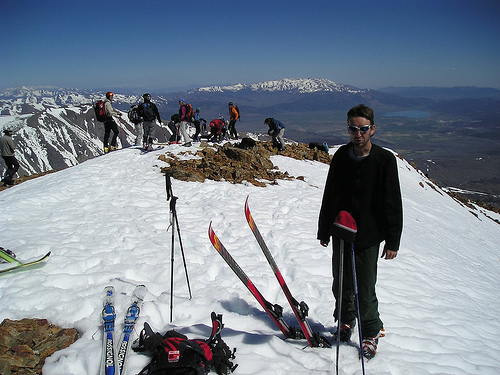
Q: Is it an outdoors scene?
A: Yes, it is outdoors.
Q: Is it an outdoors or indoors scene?
A: It is outdoors.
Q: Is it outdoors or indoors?
A: It is outdoors.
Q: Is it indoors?
A: No, it is outdoors.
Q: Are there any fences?
A: No, there are no fences.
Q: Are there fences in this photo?
A: No, there are no fences.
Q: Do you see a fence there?
A: No, there are no fences.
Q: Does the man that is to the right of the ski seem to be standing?
A: Yes, the man is standing.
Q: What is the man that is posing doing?
A: The man is standing.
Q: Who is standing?
A: The man is standing.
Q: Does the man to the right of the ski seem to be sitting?
A: No, the man is standing.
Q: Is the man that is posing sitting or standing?
A: The man is standing.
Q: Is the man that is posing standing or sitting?
A: The man is standing.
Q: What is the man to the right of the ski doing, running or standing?
A: The man is standing.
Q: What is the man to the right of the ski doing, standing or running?
A: The man is standing.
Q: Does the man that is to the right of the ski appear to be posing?
A: Yes, the man is posing.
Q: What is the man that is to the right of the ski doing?
A: The man is posing.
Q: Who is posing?
A: The man is posing.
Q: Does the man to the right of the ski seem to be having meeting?
A: No, the man is posing.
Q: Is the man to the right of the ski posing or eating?
A: The man is posing.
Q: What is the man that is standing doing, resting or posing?
A: The man is posing.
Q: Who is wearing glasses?
A: The man is wearing glasses.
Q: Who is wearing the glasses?
A: The man is wearing glasses.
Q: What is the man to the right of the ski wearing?
A: The man is wearing glasses.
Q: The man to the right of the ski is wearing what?
A: The man is wearing glasses.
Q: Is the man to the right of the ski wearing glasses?
A: Yes, the man is wearing glasses.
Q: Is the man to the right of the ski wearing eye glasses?
A: No, the man is wearing glasses.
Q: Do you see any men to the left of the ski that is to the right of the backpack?
A: No, the man is to the right of the ski.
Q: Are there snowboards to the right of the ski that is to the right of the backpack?
A: No, there is a man to the right of the ski.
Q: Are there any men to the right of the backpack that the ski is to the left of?
A: Yes, there is a man to the right of the backpack.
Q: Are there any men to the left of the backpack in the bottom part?
A: No, the man is to the right of the backpack.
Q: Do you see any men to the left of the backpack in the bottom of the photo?
A: No, the man is to the right of the backpack.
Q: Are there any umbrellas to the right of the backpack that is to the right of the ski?
A: No, there is a man to the right of the backpack.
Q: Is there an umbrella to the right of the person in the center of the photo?
A: No, there is a man to the right of the person.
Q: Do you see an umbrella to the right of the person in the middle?
A: No, there is a man to the right of the person.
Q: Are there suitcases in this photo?
A: No, there are no suitcases.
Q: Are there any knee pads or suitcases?
A: No, there are no suitcases or knee pads.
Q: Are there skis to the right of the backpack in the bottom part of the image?
A: Yes, there is a ski to the right of the backpack.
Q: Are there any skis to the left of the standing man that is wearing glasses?
A: Yes, there is a ski to the left of the man.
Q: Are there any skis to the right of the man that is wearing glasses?
A: No, the ski is to the left of the man.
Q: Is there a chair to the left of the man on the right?
A: No, there is a ski to the left of the man.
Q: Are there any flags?
A: No, there are no flags.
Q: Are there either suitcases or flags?
A: No, there are no flags or suitcases.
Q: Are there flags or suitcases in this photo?
A: No, there are no flags or suitcases.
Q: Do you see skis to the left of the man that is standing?
A: Yes, there is a ski to the left of the man.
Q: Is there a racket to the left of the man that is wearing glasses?
A: No, there is a ski to the left of the man.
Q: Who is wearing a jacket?
A: The man is wearing a jacket.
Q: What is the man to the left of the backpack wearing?
A: The man is wearing a jacket.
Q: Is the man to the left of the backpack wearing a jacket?
A: Yes, the man is wearing a jacket.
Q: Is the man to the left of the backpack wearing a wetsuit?
A: No, the man is wearing a jacket.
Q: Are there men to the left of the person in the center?
A: Yes, there is a man to the left of the person.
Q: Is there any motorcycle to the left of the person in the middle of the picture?
A: No, there is a man to the left of the person.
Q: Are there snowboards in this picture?
A: No, there are no snowboards.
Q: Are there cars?
A: No, there are no cars.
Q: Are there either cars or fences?
A: No, there are no cars or fences.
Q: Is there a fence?
A: No, there are no fences.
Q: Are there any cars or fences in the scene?
A: No, there are no fences or cars.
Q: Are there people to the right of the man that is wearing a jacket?
A: Yes, there is a person to the right of the man.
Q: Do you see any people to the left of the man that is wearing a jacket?
A: No, the person is to the right of the man.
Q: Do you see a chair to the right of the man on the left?
A: No, there is a person to the right of the man.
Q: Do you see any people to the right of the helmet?
A: Yes, there is a person to the right of the helmet.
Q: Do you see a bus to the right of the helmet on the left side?
A: No, there is a person to the right of the helmet.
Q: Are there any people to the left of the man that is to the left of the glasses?
A: Yes, there is a person to the left of the man.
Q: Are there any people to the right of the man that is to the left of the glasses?
A: No, the person is to the left of the man.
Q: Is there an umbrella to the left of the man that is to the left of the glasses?
A: No, there is a person to the left of the man.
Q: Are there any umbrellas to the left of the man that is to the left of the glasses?
A: No, there is a person to the left of the man.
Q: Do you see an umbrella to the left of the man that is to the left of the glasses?
A: No, there is a person to the left of the man.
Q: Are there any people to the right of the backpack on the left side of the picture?
A: Yes, there is a person to the right of the backpack.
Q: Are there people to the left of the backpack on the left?
A: No, the person is to the right of the backpack.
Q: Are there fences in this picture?
A: No, there are no fences.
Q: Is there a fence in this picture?
A: No, there are no fences.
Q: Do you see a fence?
A: No, there are no fences.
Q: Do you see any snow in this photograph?
A: Yes, there is snow.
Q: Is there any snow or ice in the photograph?
A: Yes, there is snow.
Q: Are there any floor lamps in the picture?
A: No, there are no floor lamps.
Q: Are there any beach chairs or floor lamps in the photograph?
A: No, there are no floor lamps or beach chairs.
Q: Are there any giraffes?
A: No, there are no giraffes.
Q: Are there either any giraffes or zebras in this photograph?
A: No, there are no giraffes or zebras.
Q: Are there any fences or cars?
A: No, there are no cars or fences.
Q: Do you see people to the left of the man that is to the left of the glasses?
A: Yes, there is a person to the left of the man.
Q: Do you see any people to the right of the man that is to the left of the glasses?
A: No, the person is to the left of the man.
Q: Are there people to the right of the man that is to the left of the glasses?
A: No, the person is to the left of the man.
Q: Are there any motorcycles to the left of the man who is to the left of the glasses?
A: No, there is a person to the left of the man.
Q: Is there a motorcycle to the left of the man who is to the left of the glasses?
A: No, there is a person to the left of the man.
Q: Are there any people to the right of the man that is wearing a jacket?
A: Yes, there is a person to the right of the man.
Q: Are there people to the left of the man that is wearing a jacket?
A: No, the person is to the right of the man.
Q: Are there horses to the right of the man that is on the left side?
A: No, there is a person to the right of the man.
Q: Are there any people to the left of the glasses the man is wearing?
A: Yes, there is a person to the left of the glasses.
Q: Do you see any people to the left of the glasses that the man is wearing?
A: Yes, there is a person to the left of the glasses.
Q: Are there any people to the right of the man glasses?
A: No, the person is to the left of the glasses.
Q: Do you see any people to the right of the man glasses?
A: No, the person is to the left of the glasses.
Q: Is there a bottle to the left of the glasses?
A: No, there is a person to the left of the glasses.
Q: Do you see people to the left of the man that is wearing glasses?
A: Yes, there is a person to the left of the man.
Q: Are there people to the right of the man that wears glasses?
A: No, the person is to the left of the man.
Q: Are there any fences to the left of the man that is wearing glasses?
A: No, there is a person to the left of the man.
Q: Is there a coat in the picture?
A: Yes, there is a coat.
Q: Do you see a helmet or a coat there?
A: Yes, there is a coat.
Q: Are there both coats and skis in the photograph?
A: Yes, there are both a coat and skis.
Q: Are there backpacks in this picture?
A: Yes, there is a backpack.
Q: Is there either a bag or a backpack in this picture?
A: Yes, there is a backpack.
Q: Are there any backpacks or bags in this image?
A: Yes, there is a backpack.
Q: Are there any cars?
A: No, there are no cars.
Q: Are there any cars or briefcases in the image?
A: No, there are no cars or briefcases.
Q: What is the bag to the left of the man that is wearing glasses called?
A: The bag is a backpack.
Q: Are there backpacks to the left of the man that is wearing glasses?
A: Yes, there is a backpack to the left of the man.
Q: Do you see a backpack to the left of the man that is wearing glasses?
A: Yes, there is a backpack to the left of the man.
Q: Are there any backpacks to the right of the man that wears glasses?
A: No, the backpack is to the left of the man.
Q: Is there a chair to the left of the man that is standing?
A: No, there is a backpack to the left of the man.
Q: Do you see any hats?
A: Yes, there is a hat.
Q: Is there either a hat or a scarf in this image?
A: Yes, there is a hat.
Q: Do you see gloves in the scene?
A: No, there are no gloves.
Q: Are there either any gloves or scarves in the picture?
A: No, there are no gloves or scarves.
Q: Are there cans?
A: No, there are no cans.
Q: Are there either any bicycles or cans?
A: No, there are no cans or bicycles.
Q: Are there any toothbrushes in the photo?
A: No, there are no toothbrushes.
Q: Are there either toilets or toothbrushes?
A: No, there are no toothbrushes or toilets.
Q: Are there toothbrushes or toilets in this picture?
A: No, there are no toothbrushes or toilets.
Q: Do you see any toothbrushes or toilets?
A: No, there are no toothbrushes or toilets.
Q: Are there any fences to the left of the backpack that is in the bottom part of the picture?
A: No, there is a ski to the left of the backpack.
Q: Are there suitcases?
A: No, there are no suitcases.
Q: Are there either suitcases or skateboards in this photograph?
A: No, there are no suitcases or skateboards.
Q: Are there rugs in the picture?
A: No, there are no rugs.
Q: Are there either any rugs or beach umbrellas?
A: No, there are no rugs or beach umbrellas.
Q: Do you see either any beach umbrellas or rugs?
A: No, there are no rugs or beach umbrellas.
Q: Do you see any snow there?
A: Yes, there is snow.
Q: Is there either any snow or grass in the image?
A: Yes, there is snow.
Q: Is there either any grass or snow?
A: Yes, there is snow.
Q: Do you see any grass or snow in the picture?
A: Yes, there is snow.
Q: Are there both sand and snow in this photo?
A: No, there is snow but no sand.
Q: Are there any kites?
A: No, there are no kites.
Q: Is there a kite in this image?
A: No, there are no kites.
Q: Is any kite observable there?
A: No, there are no kites.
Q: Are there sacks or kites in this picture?
A: No, there are no kites or sacks.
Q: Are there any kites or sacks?
A: No, there are no kites or sacks.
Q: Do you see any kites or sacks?
A: No, there are no kites or sacks.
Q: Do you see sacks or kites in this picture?
A: No, there are no kites or sacks.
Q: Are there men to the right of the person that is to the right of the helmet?
A: Yes, there is a man to the right of the person.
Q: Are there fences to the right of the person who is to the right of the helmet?
A: No, there is a man to the right of the person.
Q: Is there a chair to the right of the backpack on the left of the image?
A: No, there is a man to the right of the backpack.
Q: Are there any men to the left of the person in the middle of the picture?
A: Yes, there is a man to the left of the person.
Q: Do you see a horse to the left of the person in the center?
A: No, there is a man to the left of the person.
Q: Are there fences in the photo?
A: No, there are no fences.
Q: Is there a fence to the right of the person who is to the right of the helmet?
A: No, there is a man to the right of the person.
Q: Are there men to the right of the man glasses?
A: No, the man is to the left of the glasses.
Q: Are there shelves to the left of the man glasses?
A: No, there is a man to the left of the glasses.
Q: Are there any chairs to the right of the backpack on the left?
A: No, there is a man to the right of the backpack.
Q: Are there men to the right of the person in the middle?
A: Yes, there is a man to the right of the person.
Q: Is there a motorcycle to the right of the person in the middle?
A: No, there is a man to the right of the person.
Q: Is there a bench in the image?
A: No, there are no benches.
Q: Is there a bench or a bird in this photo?
A: No, there are no benches or birds.